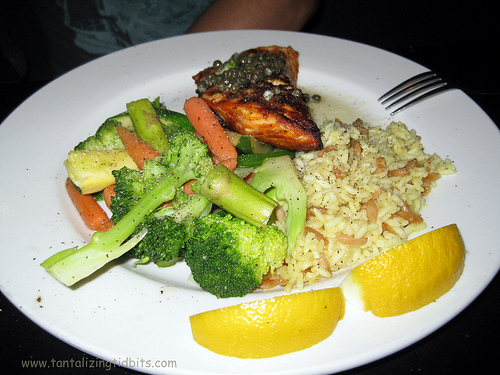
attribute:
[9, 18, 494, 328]
plate — ceramic, white, circular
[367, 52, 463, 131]
fork — upside-down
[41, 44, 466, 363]
meal — complete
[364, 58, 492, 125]
metal fork — silver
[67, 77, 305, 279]
broccoli — some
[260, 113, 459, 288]
rice — yellow, brown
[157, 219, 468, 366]
lemon — peice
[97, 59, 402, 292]
food — peppered, salted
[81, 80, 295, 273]
broccoli — chopped, green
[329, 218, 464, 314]
lemon — wedge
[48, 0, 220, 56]
shirt — blue